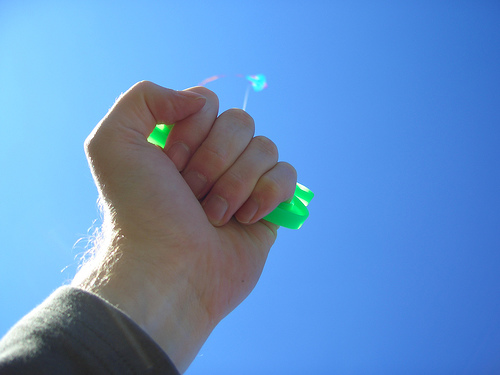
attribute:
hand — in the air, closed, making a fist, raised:
[81, 78, 298, 308]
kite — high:
[195, 68, 268, 114]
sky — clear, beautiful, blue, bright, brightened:
[0, 0, 499, 373]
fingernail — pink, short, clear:
[203, 193, 227, 223]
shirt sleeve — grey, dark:
[0, 274, 179, 374]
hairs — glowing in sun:
[49, 197, 110, 283]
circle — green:
[3, 3, 117, 178]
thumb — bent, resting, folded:
[94, 82, 206, 145]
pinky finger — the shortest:
[235, 159, 297, 225]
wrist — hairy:
[67, 230, 213, 365]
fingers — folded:
[80, 82, 298, 229]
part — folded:
[245, 72, 271, 97]